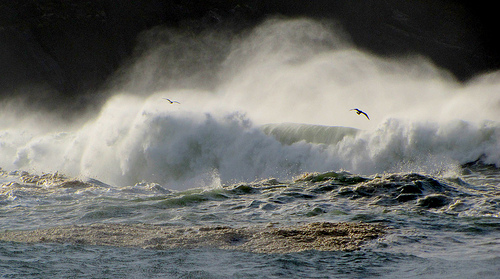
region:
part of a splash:
[196, 120, 236, 163]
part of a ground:
[263, 200, 306, 262]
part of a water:
[323, 177, 356, 203]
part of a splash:
[245, 147, 322, 257]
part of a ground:
[291, 221, 316, 253]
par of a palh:
[328, 128, 382, 225]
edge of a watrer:
[218, 168, 236, 185]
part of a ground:
[298, 230, 328, 274]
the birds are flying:
[143, 81, 395, 156]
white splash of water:
[98, 75, 408, 179]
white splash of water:
[66, 53, 450, 230]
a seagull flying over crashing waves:
[348, 105, 371, 120]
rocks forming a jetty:
[0, 220, 385, 251]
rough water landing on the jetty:
[1, 171, 93, 192]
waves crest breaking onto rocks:
[186, 118, 498, 180]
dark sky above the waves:
[1, 1, 217, 86]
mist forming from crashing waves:
[126, 18, 498, 98]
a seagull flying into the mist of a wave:
[163, 95, 182, 108]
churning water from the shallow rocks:
[252, 170, 486, 219]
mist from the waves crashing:
[0, 33, 228, 128]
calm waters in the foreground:
[1, 250, 499, 277]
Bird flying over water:
[347, 98, 374, 128]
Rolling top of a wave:
[255, 120, 354, 157]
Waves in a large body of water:
[197, 188, 318, 238]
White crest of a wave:
[104, 104, 191, 159]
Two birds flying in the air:
[152, 74, 374, 132]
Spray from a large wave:
[247, 18, 312, 45]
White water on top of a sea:
[364, 243, 442, 275]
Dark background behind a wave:
[422, 17, 464, 68]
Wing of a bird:
[362, 107, 371, 121]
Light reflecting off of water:
[157, 209, 362, 254]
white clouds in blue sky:
[11, 19, 68, 90]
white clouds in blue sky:
[79, 23, 137, 92]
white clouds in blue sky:
[164, 19, 240, 81]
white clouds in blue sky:
[208, 15, 260, 57]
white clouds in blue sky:
[273, 14, 326, 86]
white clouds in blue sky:
[311, 36, 375, 108]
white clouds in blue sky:
[368, 31, 420, 100]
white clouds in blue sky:
[420, 31, 478, 96]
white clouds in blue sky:
[34, 15, 126, 94]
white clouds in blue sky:
[191, 31, 232, 73]